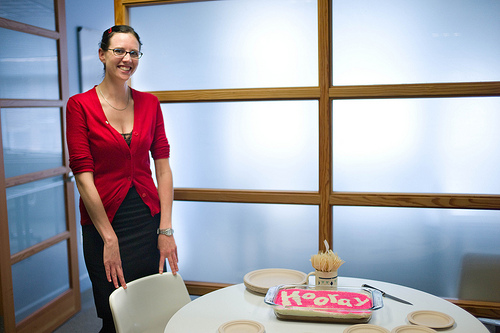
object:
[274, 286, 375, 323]
cake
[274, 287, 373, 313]
frosting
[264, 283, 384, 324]
pan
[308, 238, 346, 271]
forks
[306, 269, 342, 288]
mug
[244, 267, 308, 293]
plates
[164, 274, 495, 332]
table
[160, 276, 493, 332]
tablecloth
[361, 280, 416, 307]
knife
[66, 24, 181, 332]
woman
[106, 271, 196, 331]
chair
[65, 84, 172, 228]
cardigan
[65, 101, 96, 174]
sleeves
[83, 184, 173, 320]
dress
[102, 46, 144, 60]
glasses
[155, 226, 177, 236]
watch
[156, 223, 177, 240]
wrist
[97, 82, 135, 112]
necklace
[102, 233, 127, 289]
hands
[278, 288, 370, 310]
word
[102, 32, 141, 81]
face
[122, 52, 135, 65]
nose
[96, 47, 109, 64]
ear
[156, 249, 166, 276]
fingers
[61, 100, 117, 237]
arms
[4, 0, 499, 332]
panel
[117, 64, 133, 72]
teeth